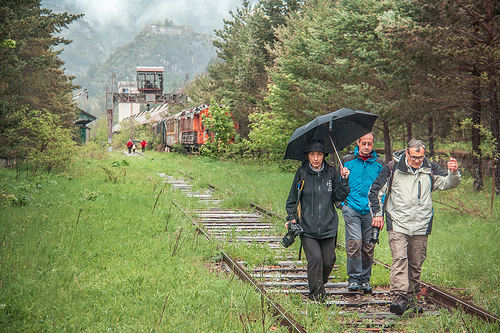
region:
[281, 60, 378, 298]
woman holding an umbrella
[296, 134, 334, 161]
woman wearing a hat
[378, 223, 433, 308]
man's pants are brown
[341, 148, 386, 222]
man's jacket is blue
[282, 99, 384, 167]
the umbrella is black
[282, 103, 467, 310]
people walking on tracks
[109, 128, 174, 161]
people walking in distance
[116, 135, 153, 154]
people are wearing red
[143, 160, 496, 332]
grass is covering the tracks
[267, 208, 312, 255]
woman holding black object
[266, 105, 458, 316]
people walking on an abandoned train track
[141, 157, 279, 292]
overgrown train track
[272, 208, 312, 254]
digital camera with a large lens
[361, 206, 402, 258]
a black camera lens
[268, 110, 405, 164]
a black umbrella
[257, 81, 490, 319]
three photographers walking on train tracks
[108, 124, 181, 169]
a family near an old train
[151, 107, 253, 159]
old abandoned train cars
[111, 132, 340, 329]
abandoned train tracks in a forest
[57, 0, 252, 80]
fog covering the mountains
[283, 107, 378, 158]
Black umbrella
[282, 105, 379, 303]
Woman is holding black umbrella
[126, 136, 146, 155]
Two men in red jackets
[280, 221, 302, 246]
Camera in woman's hand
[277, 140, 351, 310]
Woman is carrying large photography camera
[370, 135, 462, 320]
Man in gray jacket and glasses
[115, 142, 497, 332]
Train tracks through a hilly landscape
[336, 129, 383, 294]
Man in blue jacket walking on railroad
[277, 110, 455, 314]
Three photographers walking on railroad tracks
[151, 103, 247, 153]
Orange train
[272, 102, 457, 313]
people walking on a train track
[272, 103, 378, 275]
a woman holding an umbrella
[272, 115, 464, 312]
Three people walking on a train track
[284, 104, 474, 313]
Three people wearing jackets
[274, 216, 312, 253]
A woman holding a camera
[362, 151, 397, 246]
A man holding a camera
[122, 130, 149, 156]
People in the distance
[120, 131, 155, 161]
People near a train on the tracks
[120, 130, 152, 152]
Two people wearing red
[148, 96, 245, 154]
A train in the distance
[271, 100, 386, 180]
black umbrella covering man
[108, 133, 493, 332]
old railroad tracks in woods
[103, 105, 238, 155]
old train cars in woods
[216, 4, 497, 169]
large green and brown trees in woods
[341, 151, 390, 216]
blue and black jacket on man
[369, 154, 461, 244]
dark gray and light gray jacket on man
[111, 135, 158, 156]
group of people looking at train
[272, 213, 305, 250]
large camera in man's hand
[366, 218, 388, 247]
man holding lens for camera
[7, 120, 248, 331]
green grass in woods